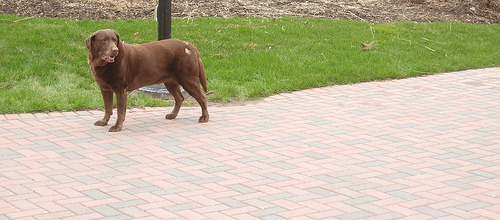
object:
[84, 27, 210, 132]
dog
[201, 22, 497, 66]
grass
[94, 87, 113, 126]
leg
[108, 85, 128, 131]
leg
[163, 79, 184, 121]
leg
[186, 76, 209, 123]
leg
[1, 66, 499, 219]
ground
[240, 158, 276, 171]
brick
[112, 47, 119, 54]
nose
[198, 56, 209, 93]
tail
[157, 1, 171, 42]
pole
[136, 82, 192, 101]
bottom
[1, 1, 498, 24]
grass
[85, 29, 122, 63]
head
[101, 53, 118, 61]
mouth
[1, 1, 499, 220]
scene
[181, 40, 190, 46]
spot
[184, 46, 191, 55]
spot